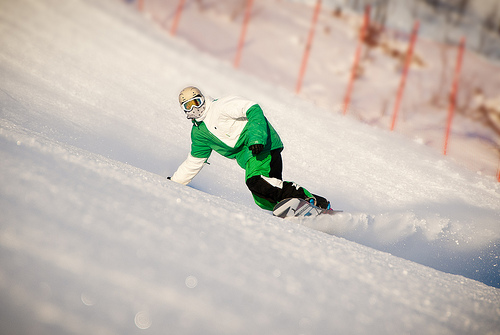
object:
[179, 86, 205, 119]
helmet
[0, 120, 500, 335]
hill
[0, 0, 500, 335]
mountains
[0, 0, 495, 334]
slope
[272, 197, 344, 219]
snowboard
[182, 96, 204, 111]
goggles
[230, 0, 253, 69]
pole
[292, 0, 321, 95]
pole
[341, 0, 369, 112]
pole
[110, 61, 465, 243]
ice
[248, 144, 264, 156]
glove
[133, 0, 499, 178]
netting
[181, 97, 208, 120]
face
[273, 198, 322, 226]
writing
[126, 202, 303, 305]
snow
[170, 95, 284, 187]
jacket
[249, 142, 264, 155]
hand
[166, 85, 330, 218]
man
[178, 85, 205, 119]
face gear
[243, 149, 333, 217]
pants